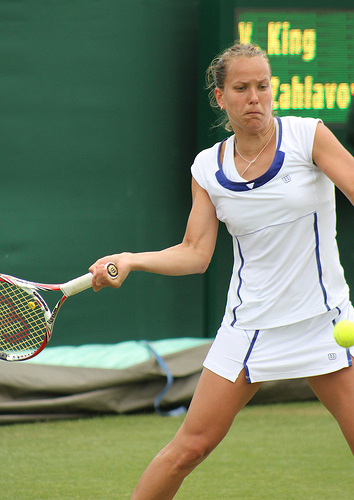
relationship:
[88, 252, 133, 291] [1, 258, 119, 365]
hand holding racket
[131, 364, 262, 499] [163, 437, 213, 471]
leg has knee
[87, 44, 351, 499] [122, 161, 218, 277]
player has arm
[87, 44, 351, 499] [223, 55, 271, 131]
player has face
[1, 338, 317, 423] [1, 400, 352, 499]
tarp on grass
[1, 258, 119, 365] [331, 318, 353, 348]
racket swinging at ball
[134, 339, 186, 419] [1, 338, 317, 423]
strap on tarp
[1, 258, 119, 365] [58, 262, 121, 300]
racket has handle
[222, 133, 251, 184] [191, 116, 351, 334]
tank under top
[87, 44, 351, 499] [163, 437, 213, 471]
player has knee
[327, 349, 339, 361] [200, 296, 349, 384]
logo on skirt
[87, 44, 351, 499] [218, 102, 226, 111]
player wearing earring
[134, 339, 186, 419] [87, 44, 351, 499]
strap behind player